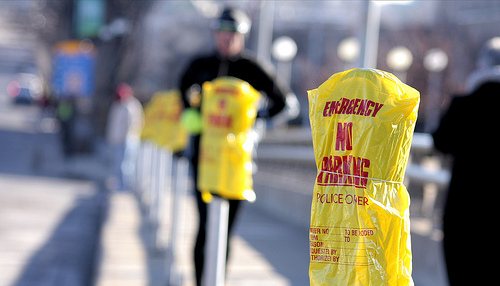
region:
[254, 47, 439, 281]
yellow parking meter cover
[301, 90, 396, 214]
yellow cover with red writing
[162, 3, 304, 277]
man standing by the road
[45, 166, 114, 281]
shadow on the ground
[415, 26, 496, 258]
person walking in a black coat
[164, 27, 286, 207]
person in a black uniform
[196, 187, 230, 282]
metal pole on the parking meter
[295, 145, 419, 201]
white rope around yellow plastic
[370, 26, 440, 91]
lights off of the street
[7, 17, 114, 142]
a blue sign by the road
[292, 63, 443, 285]
yellow plastic bag over a parking meter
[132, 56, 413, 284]
row of parking meters covered in plastic bags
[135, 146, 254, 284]
parking meter posts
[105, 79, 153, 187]
man walking wearing red cap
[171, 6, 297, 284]
man jogging down sidewalk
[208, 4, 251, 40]
hat of man jogging down sidewalk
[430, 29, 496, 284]
person walking up sidewalk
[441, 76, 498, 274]
black coat of person walking up sidewalk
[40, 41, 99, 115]
blue sign in the background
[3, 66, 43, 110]
car driving down the road far in the distance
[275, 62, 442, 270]
yellow plastic over the parking meter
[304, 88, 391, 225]
red writing on yellow plastic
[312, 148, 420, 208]
white string around the plastic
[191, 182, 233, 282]
metal pole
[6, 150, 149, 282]
shadows on the ground of parking meters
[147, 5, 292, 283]
police officer standing next to the parking meters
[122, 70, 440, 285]
a row of parking meters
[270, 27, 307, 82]
a light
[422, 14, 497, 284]
person in a black coat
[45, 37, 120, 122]
blue sign on the wall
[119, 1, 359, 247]
Woman who is running.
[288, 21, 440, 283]
Bag on the pole.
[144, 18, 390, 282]
Woman in black running.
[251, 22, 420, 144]
Blurry lights in the distance.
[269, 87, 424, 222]
Red words on the bag.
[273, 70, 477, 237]
Red words on the yellow bag.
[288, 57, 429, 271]
Yellow bag with red words.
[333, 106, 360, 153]
Red "NO" on the sign.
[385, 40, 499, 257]
person in black.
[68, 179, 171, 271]
Road behind the sign.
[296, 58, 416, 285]
plastic bag over parking meter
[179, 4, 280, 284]
person walking down the sidewalk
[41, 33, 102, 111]
blurry blue sign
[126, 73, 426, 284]
row of parking meters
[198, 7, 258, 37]
hat of man walking on sidewalk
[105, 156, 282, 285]
sidewalk parking meters are on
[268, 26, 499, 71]
row of street lights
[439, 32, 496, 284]
back of person walking down sidewalk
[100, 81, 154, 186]
person wearing red cap walking down sidewalk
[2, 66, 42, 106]
blurry car in background